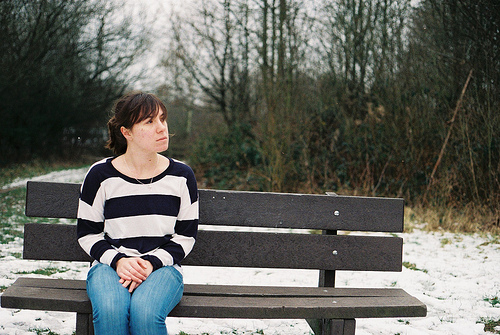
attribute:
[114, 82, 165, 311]
woman — face to the right, sitting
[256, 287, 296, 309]
bench — wood, weathered, gray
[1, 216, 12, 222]
field — snow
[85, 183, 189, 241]
sweater — black, striped, blue, long sleeve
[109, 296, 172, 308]
jeans — blue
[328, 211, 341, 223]
bolts — silver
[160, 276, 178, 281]
pants — blue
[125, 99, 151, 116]
hair — ponytail, brown, up, black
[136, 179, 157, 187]
necklace — worn, small, silver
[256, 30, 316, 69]
trees — green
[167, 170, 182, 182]
shirt — striped, black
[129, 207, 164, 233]
stripes — white